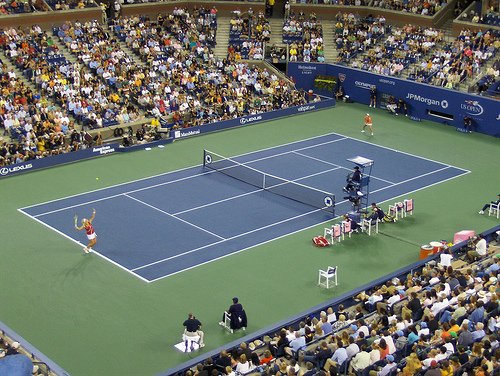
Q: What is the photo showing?
A: It is showing a stadium.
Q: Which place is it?
A: It is a stadium.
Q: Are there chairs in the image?
A: Yes, there is a chair.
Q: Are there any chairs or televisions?
A: Yes, there is a chair.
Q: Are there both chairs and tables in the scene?
A: No, there is a chair but no tables.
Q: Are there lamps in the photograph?
A: No, there are no lamps.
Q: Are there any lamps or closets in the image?
A: No, there are no lamps or closets.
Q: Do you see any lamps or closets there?
A: No, there are no lamps or closets.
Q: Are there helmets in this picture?
A: No, there are no helmets.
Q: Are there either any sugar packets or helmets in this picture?
A: No, there are no helmets or sugar packets.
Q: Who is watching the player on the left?
A: The audience is watching the player.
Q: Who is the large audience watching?
A: The audience is watching the player.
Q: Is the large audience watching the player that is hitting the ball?
A: Yes, the audience is watching the player.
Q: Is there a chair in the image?
A: Yes, there is a chair.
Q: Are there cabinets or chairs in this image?
A: Yes, there is a chair.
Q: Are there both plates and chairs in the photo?
A: No, there is a chair but no plates.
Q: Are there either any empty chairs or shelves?
A: Yes, there is an empty chair.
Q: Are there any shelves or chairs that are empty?
A: Yes, the chair is empty.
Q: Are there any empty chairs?
A: Yes, there is an empty chair.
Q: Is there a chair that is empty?
A: Yes, there is a chair that is empty.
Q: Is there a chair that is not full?
A: Yes, there is a empty chair.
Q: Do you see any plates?
A: No, there are no plates.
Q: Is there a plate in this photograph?
A: No, there are no plates.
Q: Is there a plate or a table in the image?
A: No, there are no plates or tables.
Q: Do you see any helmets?
A: No, there are no helmets.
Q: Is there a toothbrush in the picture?
A: No, there are no toothbrushes.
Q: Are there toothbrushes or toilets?
A: No, there are no toothbrushes or toilets.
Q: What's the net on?
A: The net is on the pole.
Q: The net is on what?
A: The net is on the pole.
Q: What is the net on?
A: The net is on the pole.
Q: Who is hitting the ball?
A: The player is hitting the ball.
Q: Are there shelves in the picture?
A: No, there are no shelves.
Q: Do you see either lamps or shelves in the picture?
A: No, there are no shelves or lamps.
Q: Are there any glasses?
A: No, there are no glasses.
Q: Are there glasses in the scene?
A: No, there are no glasses.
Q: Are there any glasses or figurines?
A: No, there are no glasses or figurines.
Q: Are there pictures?
A: No, there are no pictures.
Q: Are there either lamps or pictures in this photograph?
A: No, there are no pictures or lamps.